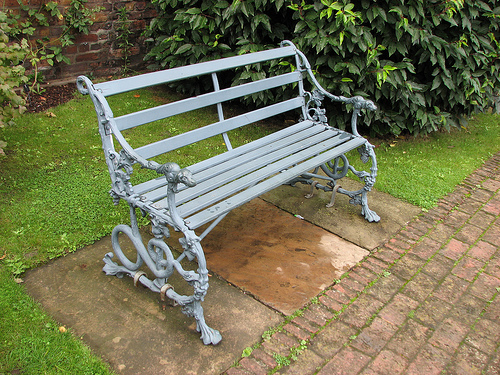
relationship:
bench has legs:
[69, 38, 383, 346] [104, 146, 386, 344]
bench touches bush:
[69, 38, 383, 346] [141, 4, 492, 129]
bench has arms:
[69, 38, 383, 346] [115, 90, 377, 207]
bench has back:
[69, 38, 383, 346] [86, 45, 309, 177]